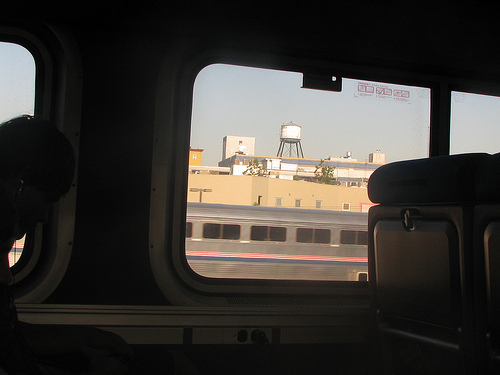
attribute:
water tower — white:
[273, 123, 309, 150]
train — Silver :
[189, 200, 369, 257]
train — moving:
[92, 6, 472, 59]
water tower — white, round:
[276, 118, 307, 156]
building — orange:
[270, 180, 354, 200]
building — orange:
[211, 179, 246, 198]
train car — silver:
[196, 210, 359, 223]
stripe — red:
[210, 252, 272, 256]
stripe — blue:
[273, 261, 325, 266]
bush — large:
[317, 167, 341, 182]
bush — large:
[249, 167, 269, 176]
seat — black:
[376, 164, 481, 190]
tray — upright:
[381, 235, 437, 316]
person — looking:
[5, 146, 9, 363]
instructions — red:
[360, 86, 405, 98]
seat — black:
[484, 166, 499, 195]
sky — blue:
[330, 107, 412, 140]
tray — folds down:
[358, 206, 471, 346]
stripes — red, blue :
[185, 242, 387, 269]